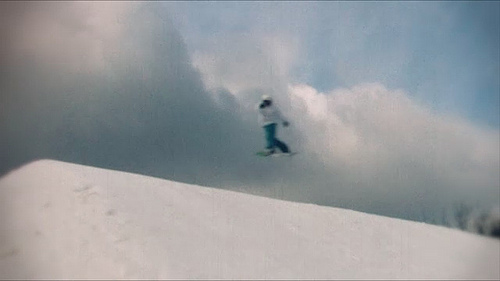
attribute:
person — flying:
[256, 94, 292, 156]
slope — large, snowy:
[2, 158, 499, 279]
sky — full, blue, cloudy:
[1, 0, 499, 127]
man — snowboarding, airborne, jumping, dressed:
[256, 92, 292, 153]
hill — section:
[0, 159, 205, 280]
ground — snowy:
[0, 200, 500, 279]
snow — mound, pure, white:
[82, 167, 142, 205]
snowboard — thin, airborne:
[252, 149, 298, 159]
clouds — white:
[2, 1, 499, 222]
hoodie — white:
[257, 94, 287, 126]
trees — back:
[443, 202, 498, 235]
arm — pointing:
[258, 102, 266, 113]